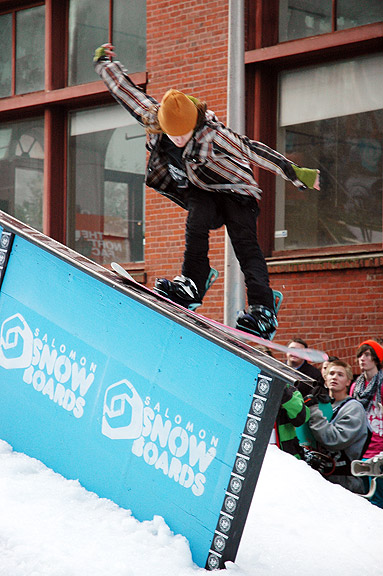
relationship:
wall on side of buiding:
[3, 5, 376, 396] [0, 0, 375, 514]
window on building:
[57, 89, 143, 266] [1, 6, 377, 515]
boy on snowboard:
[89, 41, 328, 341] [110, 258, 331, 368]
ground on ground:
[0, 440, 383, 576] [2, 436, 382, 566]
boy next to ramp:
[89, 41, 328, 341] [2, 198, 321, 572]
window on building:
[244, 44, 381, 255] [1, 6, 377, 515]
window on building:
[63, 92, 149, 266] [1, 6, 377, 515]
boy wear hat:
[93, 41, 320, 341] [153, 84, 197, 135]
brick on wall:
[286, 298, 298, 306] [262, 243, 382, 375]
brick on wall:
[305, 288, 311, 296] [262, 243, 382, 375]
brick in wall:
[176, 43, 187, 52] [145, 2, 225, 325]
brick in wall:
[156, 218, 164, 222] [145, 2, 225, 325]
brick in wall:
[161, 260, 167, 266] [145, 2, 225, 325]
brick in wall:
[166, 224, 179, 233] [145, 2, 225, 325]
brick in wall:
[153, 257, 168, 266] [145, 2, 225, 325]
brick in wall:
[305, 308, 318, 315] [262, 243, 382, 375]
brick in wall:
[339, 325, 357, 332] [262, 243, 382, 375]